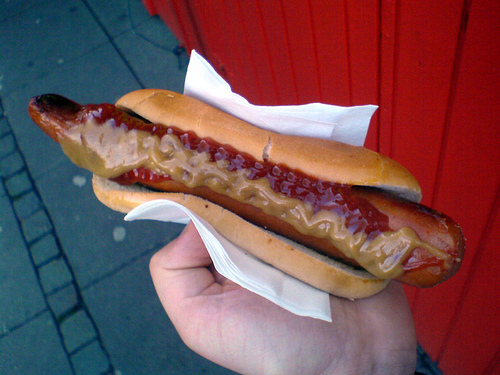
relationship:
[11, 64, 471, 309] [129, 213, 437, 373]
hot dog in hand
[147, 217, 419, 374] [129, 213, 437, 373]
person has hand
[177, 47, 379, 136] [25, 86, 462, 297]
napkin around hotdog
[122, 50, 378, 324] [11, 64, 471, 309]
napkin wrapped around hot dog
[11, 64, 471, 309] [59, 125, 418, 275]
hot dog has mustard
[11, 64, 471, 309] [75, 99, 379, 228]
hot dog has ketchup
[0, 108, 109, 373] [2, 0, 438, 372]
groundlines on ground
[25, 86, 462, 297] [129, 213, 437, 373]
hotdog in hand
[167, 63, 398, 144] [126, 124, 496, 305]
napkin under hot dog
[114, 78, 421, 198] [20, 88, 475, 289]
bun outside meat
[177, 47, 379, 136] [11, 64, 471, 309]
napkin underneath hot dog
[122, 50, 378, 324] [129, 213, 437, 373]
napkin in hand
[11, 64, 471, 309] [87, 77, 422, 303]
hot dog in bun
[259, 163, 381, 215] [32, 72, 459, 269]
ketchup drizzled on hot dog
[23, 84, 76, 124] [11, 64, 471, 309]
burnt area of hot dog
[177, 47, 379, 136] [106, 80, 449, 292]
napkin under hot dog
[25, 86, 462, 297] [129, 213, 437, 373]
hotdog held in hand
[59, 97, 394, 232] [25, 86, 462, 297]
ketchup on hotdog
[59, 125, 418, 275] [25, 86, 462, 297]
mustard on hotdog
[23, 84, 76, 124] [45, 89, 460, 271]
burnt area of hot dog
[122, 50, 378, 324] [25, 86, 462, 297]
napkin under hotdog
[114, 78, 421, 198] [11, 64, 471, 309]
bun with hot dog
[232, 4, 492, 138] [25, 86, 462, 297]
wall behind hotdog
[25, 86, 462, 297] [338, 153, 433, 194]
hotdog on bun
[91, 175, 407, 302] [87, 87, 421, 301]
bottom of hotdog bun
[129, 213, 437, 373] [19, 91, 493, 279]
hand holding hot dog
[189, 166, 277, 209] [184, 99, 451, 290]
condiment on hot dog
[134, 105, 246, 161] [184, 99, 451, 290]
condiment on hot dog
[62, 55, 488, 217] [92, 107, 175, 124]
hot dog has ketchup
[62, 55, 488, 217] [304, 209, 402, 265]
hot dog has mustard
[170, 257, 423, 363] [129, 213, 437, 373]
palm of hand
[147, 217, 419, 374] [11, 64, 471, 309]
person holding hot dog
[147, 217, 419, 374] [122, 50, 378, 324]
person using napkin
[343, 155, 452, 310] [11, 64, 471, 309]
end of hot dog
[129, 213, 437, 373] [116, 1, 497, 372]
hand of person